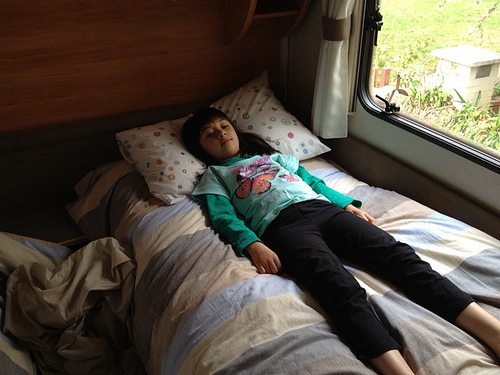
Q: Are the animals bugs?
A: Yes, all the animals are bugs.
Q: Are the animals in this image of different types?
A: No, all the animals are bugs.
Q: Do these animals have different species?
A: No, all the animals are bugs.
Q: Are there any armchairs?
A: No, there are no armchairs.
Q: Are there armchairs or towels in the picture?
A: No, there are no armchairs or towels.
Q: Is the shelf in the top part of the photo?
A: Yes, the shelf is in the top of the image.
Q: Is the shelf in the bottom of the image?
A: No, the shelf is in the top of the image.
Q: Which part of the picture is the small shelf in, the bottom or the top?
A: The shelf is in the top of the image.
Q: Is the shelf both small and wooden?
A: Yes, the shelf is small and wooden.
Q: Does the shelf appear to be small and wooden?
A: Yes, the shelf is small and wooden.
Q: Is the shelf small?
A: Yes, the shelf is small.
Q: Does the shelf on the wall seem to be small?
A: Yes, the shelf is small.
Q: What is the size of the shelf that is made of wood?
A: The shelf is small.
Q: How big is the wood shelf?
A: The shelf is small.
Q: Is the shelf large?
A: No, the shelf is small.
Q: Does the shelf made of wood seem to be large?
A: No, the shelf is small.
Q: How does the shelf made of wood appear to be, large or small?
A: The shelf is small.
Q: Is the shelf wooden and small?
A: Yes, the shelf is wooden and small.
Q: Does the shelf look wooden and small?
A: Yes, the shelf is wooden and small.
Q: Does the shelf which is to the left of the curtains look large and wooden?
A: No, the shelf is wooden but small.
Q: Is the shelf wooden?
A: Yes, the shelf is wooden.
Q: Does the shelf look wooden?
A: Yes, the shelf is wooden.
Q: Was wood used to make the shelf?
A: Yes, the shelf is made of wood.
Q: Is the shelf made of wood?
A: Yes, the shelf is made of wood.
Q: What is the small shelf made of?
A: The shelf is made of wood.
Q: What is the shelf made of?
A: The shelf is made of wood.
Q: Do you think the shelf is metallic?
A: No, the shelf is wooden.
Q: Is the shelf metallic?
A: No, the shelf is wooden.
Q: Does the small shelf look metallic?
A: No, the shelf is wooden.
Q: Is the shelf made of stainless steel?
A: No, the shelf is made of wood.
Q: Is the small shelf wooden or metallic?
A: The shelf is wooden.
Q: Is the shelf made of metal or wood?
A: The shelf is made of wood.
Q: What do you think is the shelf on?
A: The shelf is on the wall.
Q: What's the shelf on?
A: The shelf is on the wall.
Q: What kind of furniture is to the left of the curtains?
A: The piece of furniture is a shelf.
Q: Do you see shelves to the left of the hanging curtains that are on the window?
A: Yes, there is a shelf to the left of the curtains.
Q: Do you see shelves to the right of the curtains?
A: No, the shelf is to the left of the curtains.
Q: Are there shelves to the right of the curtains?
A: No, the shelf is to the left of the curtains.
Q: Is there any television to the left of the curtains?
A: No, there is a shelf to the left of the curtains.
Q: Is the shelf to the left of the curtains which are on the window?
A: Yes, the shelf is to the left of the curtains.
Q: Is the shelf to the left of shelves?
A: No, the shelf is to the left of the curtains.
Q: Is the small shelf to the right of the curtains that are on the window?
A: No, the shelf is to the left of the curtains.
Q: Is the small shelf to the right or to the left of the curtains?
A: The shelf is to the left of the curtains.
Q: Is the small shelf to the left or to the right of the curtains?
A: The shelf is to the left of the curtains.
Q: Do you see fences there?
A: No, there are no fences.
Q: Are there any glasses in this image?
A: No, there are no glasses.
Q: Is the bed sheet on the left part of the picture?
A: Yes, the bed sheet is on the left of the image.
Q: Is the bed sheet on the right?
A: No, the bed sheet is on the left of the image.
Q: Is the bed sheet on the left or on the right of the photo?
A: The bed sheet is on the left of the image.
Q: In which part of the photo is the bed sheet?
A: The bed sheet is on the left of the image.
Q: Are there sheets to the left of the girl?
A: Yes, there is a sheet to the left of the girl.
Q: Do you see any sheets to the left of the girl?
A: Yes, there is a sheet to the left of the girl.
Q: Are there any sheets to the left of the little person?
A: Yes, there is a sheet to the left of the girl.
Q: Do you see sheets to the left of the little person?
A: Yes, there is a sheet to the left of the girl.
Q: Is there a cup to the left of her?
A: No, there is a sheet to the left of the girl.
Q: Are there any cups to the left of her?
A: No, there is a sheet to the left of the girl.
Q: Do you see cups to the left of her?
A: No, there is a sheet to the left of the girl.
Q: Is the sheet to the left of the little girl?
A: Yes, the sheet is to the left of the girl.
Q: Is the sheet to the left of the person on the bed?
A: Yes, the sheet is to the left of the girl.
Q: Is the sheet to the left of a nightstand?
A: No, the sheet is to the left of the girl.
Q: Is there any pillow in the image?
A: Yes, there is a pillow.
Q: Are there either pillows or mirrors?
A: Yes, there is a pillow.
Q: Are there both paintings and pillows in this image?
A: No, there is a pillow but no paintings.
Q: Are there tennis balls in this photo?
A: No, there are no tennis balls.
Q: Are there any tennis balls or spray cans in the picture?
A: No, there are no tennis balls or spray cans.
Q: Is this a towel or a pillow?
A: This is a pillow.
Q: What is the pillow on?
A: The pillow is on the bed.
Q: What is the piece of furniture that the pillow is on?
A: The piece of furniture is a bed.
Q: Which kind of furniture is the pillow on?
A: The pillow is on the bed.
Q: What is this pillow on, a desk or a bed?
A: The pillow is on a bed.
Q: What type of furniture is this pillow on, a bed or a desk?
A: The pillow is on a bed.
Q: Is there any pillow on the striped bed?
A: Yes, there is a pillow on the bed.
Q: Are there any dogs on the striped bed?
A: No, there is a pillow on the bed.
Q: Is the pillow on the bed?
A: Yes, the pillow is on the bed.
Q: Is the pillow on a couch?
A: No, the pillow is on the bed.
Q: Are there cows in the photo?
A: No, there are no cows.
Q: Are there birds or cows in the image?
A: No, there are no cows or birds.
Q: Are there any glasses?
A: No, there are no glasses.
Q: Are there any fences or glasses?
A: No, there are no glasses or fences.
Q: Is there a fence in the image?
A: No, there are no fences.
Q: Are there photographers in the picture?
A: No, there are no photographers.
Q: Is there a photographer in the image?
A: No, there are no photographers.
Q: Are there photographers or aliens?
A: No, there are no photographers or aliens.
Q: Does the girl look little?
A: Yes, the girl is little.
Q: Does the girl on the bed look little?
A: Yes, the girl is little.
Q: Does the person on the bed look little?
A: Yes, the girl is little.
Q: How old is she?
A: The girl is little.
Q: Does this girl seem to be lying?
A: Yes, the girl is lying.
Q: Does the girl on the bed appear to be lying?
A: Yes, the girl is lying.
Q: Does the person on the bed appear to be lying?
A: Yes, the girl is lying.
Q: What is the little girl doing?
A: The girl is lying.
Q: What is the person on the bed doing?
A: The girl is lying.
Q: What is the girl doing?
A: The girl is lying.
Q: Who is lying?
A: The girl is lying.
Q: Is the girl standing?
A: No, the girl is lying.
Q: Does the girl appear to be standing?
A: No, the girl is lying.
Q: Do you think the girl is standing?
A: No, the girl is lying.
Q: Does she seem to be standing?
A: No, the girl is lying.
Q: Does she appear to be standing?
A: No, the girl is lying.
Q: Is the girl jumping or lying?
A: The girl is lying.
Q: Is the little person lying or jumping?
A: The girl is lying.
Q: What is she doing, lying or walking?
A: The girl is lying.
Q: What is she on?
A: The girl is on the bed.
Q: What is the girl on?
A: The girl is on the bed.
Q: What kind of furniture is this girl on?
A: The girl is on the bed.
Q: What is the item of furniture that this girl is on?
A: The piece of furniture is a bed.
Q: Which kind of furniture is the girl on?
A: The girl is on the bed.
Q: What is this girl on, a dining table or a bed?
A: The girl is on a bed.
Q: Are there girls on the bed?
A: Yes, there is a girl on the bed.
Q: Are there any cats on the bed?
A: No, there is a girl on the bed.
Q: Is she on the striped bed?
A: Yes, the girl is on the bed.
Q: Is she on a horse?
A: No, the girl is on the bed.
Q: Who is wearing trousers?
A: The girl is wearing trousers.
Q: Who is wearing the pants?
A: The girl is wearing trousers.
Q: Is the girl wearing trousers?
A: Yes, the girl is wearing trousers.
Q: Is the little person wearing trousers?
A: Yes, the girl is wearing trousers.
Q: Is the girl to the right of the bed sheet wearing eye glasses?
A: No, the girl is wearing trousers.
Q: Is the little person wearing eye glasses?
A: No, the girl is wearing trousers.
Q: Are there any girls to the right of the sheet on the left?
A: Yes, there is a girl to the right of the bed sheet.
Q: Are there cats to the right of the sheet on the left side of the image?
A: No, there is a girl to the right of the sheet.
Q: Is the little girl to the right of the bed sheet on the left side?
A: Yes, the girl is to the right of the sheet.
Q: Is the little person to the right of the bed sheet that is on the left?
A: Yes, the girl is to the right of the sheet.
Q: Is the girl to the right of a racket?
A: No, the girl is to the right of the sheet.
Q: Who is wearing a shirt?
A: The girl is wearing a shirt.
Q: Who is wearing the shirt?
A: The girl is wearing a shirt.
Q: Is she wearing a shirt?
A: Yes, the girl is wearing a shirt.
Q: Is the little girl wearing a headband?
A: No, the girl is wearing a shirt.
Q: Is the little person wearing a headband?
A: No, the girl is wearing a shirt.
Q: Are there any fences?
A: No, there are no fences.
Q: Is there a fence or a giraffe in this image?
A: No, there are no fences or giraffes.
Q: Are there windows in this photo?
A: Yes, there is a window.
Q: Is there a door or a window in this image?
A: Yes, there is a window.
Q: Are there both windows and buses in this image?
A: No, there is a window but no buses.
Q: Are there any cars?
A: No, there are no cars.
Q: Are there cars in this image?
A: No, there are no cars.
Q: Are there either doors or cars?
A: No, there are no cars or doors.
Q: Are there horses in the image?
A: No, there are no horses.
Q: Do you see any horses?
A: No, there are no horses.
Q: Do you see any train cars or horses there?
A: No, there are no horses or train cars.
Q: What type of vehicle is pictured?
A: The vehicle is a trailer.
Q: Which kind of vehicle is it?
A: The vehicle is a trailer.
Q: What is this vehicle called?
A: That is a trailer.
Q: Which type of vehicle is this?
A: That is a trailer.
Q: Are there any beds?
A: Yes, there is a bed.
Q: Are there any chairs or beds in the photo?
A: Yes, there is a bed.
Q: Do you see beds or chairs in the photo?
A: Yes, there is a bed.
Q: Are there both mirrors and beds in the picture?
A: No, there is a bed but no mirrors.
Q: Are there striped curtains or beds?
A: Yes, there is a striped bed.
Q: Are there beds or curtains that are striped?
A: Yes, the bed is striped.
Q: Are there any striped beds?
A: Yes, there is a striped bed.